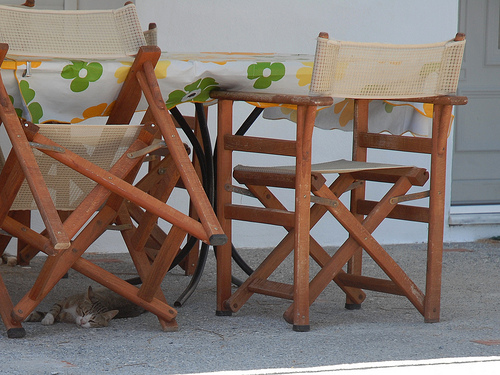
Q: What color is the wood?
A: Brown.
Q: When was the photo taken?
A: Daytime.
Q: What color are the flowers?
A: Orange, Green and Yellow.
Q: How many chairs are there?
A: Two.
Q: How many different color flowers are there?
A: Three.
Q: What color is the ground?
A: Gray.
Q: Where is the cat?
A: Below the table.